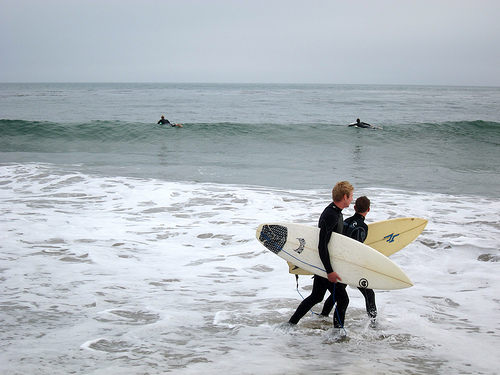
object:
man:
[289, 181, 354, 328]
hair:
[355, 196, 371, 213]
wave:
[0, 118, 500, 146]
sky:
[0, 0, 499, 85]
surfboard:
[256, 222, 414, 290]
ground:
[441, 197, 499, 231]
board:
[288, 217, 429, 276]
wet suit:
[320, 213, 377, 317]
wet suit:
[289, 202, 350, 328]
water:
[230, 130, 320, 177]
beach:
[0, 223, 497, 374]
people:
[157, 115, 182, 128]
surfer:
[289, 181, 353, 329]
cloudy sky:
[6, 1, 326, 38]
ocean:
[0, 81, 499, 374]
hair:
[332, 180, 354, 202]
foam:
[0, 159, 499, 375]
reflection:
[351, 142, 363, 161]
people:
[348, 118, 381, 130]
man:
[319, 196, 377, 337]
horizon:
[1, 73, 500, 91]